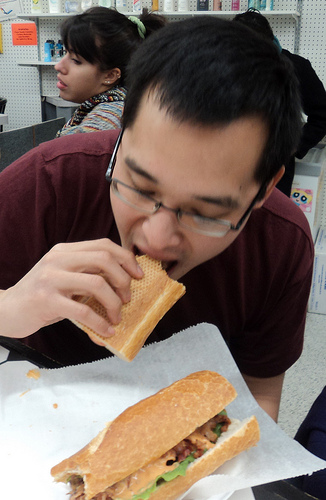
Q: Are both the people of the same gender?
A: No, they are both male and female.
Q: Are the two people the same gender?
A: No, they are both male and female.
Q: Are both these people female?
A: No, they are both male and female.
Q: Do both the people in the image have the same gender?
A: No, they are both male and female.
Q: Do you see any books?
A: No, there are no books.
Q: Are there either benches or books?
A: No, there are no books or benches.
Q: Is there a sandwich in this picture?
A: Yes, there is a sandwich.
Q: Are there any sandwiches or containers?
A: Yes, there is a sandwich.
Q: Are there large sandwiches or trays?
A: Yes, there is a large sandwich.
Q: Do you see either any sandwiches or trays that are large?
A: Yes, the sandwich is large.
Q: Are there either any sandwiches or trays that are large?
A: Yes, the sandwich is large.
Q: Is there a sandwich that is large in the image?
A: Yes, there is a large sandwich.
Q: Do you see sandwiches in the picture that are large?
A: Yes, there is a sandwich that is large.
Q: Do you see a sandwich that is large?
A: Yes, there is a sandwich that is large.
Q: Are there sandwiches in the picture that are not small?
A: Yes, there is a large sandwich.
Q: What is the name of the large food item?
A: The food item is a sandwich.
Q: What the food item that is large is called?
A: The food item is a sandwich.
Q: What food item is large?
A: The food item is a sandwich.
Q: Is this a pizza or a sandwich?
A: This is a sandwich.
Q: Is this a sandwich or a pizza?
A: This is a sandwich.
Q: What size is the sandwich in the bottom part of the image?
A: The sandwich is large.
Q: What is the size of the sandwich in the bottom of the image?
A: The sandwich is large.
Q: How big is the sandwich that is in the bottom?
A: The sandwich is large.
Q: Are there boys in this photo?
A: No, there are no boys.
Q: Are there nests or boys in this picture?
A: No, there are no boys or nests.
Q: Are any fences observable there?
A: No, there are no fences.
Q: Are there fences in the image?
A: No, there are no fences.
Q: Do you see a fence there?
A: No, there are no fences.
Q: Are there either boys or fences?
A: No, there are no fences or boys.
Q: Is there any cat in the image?
A: No, there are no cats.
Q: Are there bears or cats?
A: No, there are no cats or bears.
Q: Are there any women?
A: Yes, there is a woman.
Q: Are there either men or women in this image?
A: Yes, there is a woman.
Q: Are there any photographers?
A: No, there are no photographers.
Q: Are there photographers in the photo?
A: No, there are no photographers.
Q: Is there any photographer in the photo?
A: No, there are no photographers.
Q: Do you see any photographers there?
A: No, there are no photographers.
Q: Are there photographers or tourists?
A: No, there are no photographers or tourists.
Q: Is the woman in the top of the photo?
A: Yes, the woman is in the top of the image.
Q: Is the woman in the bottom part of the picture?
A: No, the woman is in the top of the image.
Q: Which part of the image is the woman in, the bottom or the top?
A: The woman is in the top of the image.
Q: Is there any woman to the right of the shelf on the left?
A: Yes, there is a woman to the right of the shelf.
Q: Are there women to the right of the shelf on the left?
A: Yes, there is a woman to the right of the shelf.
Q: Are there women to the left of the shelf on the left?
A: No, the woman is to the right of the shelf.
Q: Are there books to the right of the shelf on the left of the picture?
A: No, there is a woman to the right of the shelf.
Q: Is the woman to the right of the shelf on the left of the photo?
A: Yes, the woman is to the right of the shelf.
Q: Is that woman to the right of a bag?
A: No, the woman is to the right of the shelf.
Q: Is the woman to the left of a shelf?
A: No, the woman is to the right of a shelf.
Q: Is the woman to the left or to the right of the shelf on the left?
A: The woman is to the right of the shelf.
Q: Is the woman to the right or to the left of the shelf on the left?
A: The woman is to the right of the shelf.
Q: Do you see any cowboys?
A: No, there are no cowboys.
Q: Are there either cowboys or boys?
A: No, there are no cowboys or boys.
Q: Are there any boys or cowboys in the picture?
A: No, there are no cowboys or boys.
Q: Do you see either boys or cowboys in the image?
A: No, there are no cowboys or boys.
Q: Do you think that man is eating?
A: Yes, the man is eating.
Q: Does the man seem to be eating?
A: Yes, the man is eating.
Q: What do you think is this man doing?
A: The man is eating.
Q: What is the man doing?
A: The man is eating.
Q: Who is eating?
A: The man is eating.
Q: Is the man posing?
A: No, the man is eating.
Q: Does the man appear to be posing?
A: No, the man is eating.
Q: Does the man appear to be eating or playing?
A: The man is eating.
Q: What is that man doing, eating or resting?
A: The man is eating.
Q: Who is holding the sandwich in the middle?
A: The man is holding the sandwich.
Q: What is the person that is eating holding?
A: The man is holding the sandwich.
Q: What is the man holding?
A: The man is holding the sandwich.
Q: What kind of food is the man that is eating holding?
A: The man is holding the sandwich.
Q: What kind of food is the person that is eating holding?
A: The man is holding the sandwich.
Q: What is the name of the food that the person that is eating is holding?
A: The food is a sandwich.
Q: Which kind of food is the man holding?
A: The man is holding the sandwich.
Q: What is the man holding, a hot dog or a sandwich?
A: The man is holding a sandwich.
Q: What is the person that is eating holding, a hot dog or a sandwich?
A: The man is holding a sandwich.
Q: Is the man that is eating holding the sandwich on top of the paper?
A: Yes, the man is holding the sandwich.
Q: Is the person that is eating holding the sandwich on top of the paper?
A: Yes, the man is holding the sandwich.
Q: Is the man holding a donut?
A: No, the man is holding the sandwich.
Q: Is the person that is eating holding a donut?
A: No, the man is holding the sandwich.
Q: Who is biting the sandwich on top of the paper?
A: The man is biting the sandwich.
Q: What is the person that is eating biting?
A: The man is biting the sandwich.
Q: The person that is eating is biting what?
A: The man is biting the sandwich.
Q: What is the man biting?
A: The man is biting the sandwich.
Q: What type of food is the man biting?
A: The man is biting the sandwich.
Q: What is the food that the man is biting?
A: The food is a sandwich.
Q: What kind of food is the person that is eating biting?
A: The man is biting the sandwich.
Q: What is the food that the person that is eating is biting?
A: The food is a sandwich.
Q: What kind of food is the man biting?
A: The man is biting the sandwich.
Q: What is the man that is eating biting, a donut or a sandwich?
A: The man is biting a sandwich.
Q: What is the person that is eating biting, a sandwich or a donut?
A: The man is biting a sandwich.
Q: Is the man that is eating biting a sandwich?
A: Yes, the man is biting a sandwich.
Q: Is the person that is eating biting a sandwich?
A: Yes, the man is biting a sandwich.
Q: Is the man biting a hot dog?
A: No, the man is biting a sandwich.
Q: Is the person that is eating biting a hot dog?
A: No, the man is biting a sandwich.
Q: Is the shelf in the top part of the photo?
A: Yes, the shelf is in the top of the image.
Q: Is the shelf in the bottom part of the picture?
A: No, the shelf is in the top of the image.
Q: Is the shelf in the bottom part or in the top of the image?
A: The shelf is in the top of the image.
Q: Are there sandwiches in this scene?
A: Yes, there is a sandwich.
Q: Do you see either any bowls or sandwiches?
A: Yes, there is a sandwich.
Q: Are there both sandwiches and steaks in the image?
A: No, there is a sandwich but no steaks.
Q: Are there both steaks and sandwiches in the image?
A: No, there is a sandwich but no steaks.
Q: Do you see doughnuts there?
A: No, there are no doughnuts.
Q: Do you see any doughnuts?
A: No, there are no doughnuts.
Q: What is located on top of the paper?
A: The sandwich is on top of the paper.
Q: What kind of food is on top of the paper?
A: The food is a sandwich.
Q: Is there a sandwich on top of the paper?
A: Yes, there is a sandwich on top of the paper.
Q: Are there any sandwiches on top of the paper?
A: Yes, there is a sandwich on top of the paper.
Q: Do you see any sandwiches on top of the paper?
A: Yes, there is a sandwich on top of the paper.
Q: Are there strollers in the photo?
A: No, there are no strollers.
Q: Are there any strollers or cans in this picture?
A: No, there are no strollers or cans.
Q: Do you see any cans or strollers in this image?
A: No, there are no strollers or cans.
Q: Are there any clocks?
A: No, there are no clocks.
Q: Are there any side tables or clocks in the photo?
A: No, there are no clocks or side tables.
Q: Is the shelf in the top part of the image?
A: Yes, the shelf is in the top of the image.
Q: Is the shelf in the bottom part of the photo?
A: No, the shelf is in the top of the image.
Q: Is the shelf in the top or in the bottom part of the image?
A: The shelf is in the top of the image.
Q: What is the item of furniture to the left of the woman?
A: The piece of furniture is a shelf.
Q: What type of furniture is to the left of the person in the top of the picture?
A: The piece of furniture is a shelf.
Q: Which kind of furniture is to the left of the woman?
A: The piece of furniture is a shelf.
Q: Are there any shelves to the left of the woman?
A: Yes, there is a shelf to the left of the woman.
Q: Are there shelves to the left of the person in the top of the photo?
A: Yes, there is a shelf to the left of the woman.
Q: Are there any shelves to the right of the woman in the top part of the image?
A: No, the shelf is to the left of the woman.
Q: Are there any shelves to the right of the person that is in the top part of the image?
A: No, the shelf is to the left of the woman.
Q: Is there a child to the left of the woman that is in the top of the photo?
A: No, there is a shelf to the left of the woman.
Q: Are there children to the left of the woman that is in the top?
A: No, there is a shelf to the left of the woman.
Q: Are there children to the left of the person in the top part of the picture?
A: No, there is a shelf to the left of the woman.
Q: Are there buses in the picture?
A: No, there are no buses.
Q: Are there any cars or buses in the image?
A: No, there are no buses or cars.